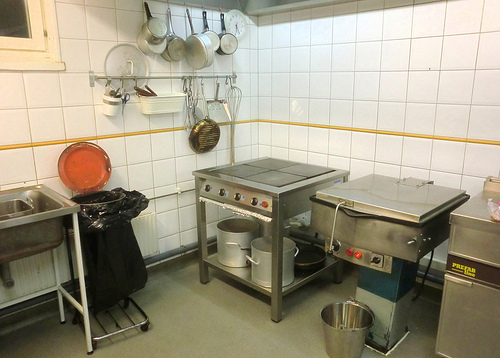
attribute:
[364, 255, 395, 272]
knob — black, small, red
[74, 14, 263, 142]
wall — silver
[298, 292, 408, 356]
pail — empt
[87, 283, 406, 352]
floor — gray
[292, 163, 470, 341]
stove — electric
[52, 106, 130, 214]
plate — orange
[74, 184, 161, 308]
can — black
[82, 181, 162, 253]
bag — black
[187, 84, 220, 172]
skillet — black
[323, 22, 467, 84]
tiles — white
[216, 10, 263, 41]
clock — white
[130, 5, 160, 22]
hadle — black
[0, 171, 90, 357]
sik — silver